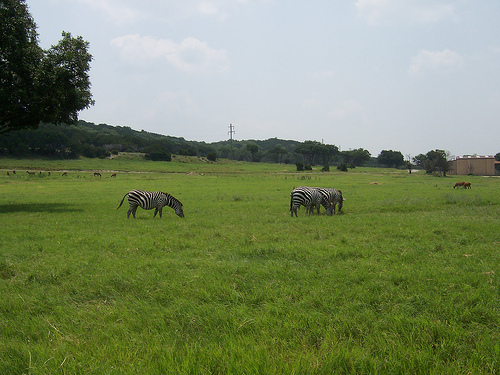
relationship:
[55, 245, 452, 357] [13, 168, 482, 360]
grass in field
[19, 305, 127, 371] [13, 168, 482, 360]
grass in field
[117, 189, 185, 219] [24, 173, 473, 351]
zebra in field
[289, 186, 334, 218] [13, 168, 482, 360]
zebra in field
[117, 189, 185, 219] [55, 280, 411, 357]
zebra in grass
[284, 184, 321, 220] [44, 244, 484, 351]
zebra in grass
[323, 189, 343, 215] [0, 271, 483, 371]
zebra in grass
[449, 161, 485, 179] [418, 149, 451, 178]
building by trees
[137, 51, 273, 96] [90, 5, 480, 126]
cloud in sky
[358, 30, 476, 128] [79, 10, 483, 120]
cloud in sky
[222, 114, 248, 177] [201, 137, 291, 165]
pole by trees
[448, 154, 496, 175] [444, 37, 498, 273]
building on side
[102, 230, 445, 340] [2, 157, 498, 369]
grass on field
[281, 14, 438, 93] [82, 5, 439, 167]
cloud in sky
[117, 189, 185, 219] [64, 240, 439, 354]
zebra standing grass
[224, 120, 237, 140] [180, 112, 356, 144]
post supporting lines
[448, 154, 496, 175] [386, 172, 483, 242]
building on premises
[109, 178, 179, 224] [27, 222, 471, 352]
zebra in field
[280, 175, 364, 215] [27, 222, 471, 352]
zebra in field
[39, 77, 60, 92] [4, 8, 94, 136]
leaves on tree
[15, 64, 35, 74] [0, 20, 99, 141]
leaves on tree